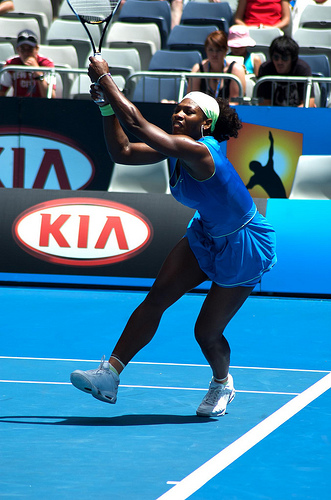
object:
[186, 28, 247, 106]
spectator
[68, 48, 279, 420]
woman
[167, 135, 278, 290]
dress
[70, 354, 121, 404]
shoe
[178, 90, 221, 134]
headband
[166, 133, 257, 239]
tank top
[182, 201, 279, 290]
skirt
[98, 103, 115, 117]
wristband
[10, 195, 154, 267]
sign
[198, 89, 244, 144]
hair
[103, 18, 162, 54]
stands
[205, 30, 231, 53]
hair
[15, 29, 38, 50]
hat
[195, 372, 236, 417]
foot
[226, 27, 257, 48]
hat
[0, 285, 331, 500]
tennis court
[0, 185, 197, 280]
black wall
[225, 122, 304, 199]
sign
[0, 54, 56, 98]
shirt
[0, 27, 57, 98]
spectator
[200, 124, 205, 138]
earring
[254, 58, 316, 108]
shirt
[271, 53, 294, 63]
sunglasses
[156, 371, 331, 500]
line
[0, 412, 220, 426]
shadow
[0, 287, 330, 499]
ground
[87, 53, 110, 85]
hand